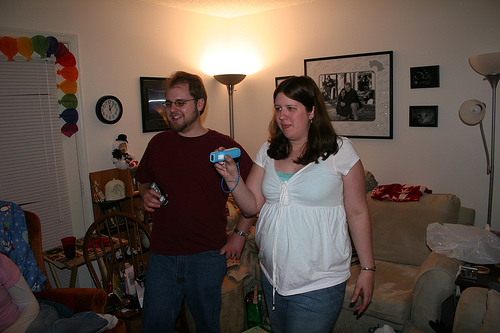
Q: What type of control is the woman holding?
A: Wii controller.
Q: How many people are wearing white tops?
A: 1.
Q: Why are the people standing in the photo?
A: Playing video game.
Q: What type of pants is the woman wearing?
A: Jeans.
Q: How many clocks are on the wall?
A: 1.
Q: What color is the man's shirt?
A: Burgundy.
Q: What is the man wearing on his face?
A: Glasses.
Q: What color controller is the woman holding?
A: Blue.